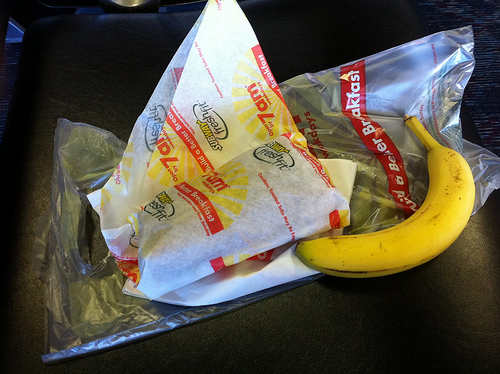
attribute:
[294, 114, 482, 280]
banana — yellow, ripe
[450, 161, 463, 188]
spot — brown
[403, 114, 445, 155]
top — stem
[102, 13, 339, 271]
wrapper — white, paper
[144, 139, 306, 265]
sandwich — wrapped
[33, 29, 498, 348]
bag — clear, plastic, long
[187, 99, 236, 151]
logo — green, yellow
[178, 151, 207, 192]
yellow — sun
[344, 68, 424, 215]
logo — red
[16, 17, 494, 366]
table — black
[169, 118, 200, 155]
words — white